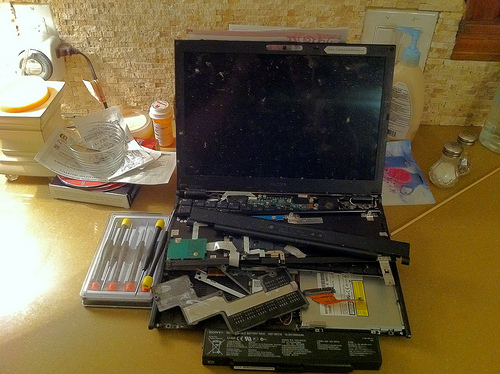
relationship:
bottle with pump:
[399, 30, 424, 138] [399, 24, 424, 71]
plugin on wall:
[51, 37, 80, 63] [123, 15, 147, 69]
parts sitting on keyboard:
[209, 221, 281, 285] [291, 259, 345, 299]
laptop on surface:
[158, 27, 421, 330] [449, 271, 479, 355]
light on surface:
[26, 223, 63, 293] [449, 271, 479, 355]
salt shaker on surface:
[426, 144, 467, 188] [449, 271, 479, 355]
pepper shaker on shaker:
[449, 131, 478, 154] [432, 142, 452, 173]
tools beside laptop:
[109, 217, 156, 294] [158, 27, 421, 330]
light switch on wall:
[368, 10, 400, 43] [123, 15, 147, 69]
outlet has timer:
[27, 14, 57, 49] [18, 47, 53, 79]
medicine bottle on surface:
[147, 97, 174, 145] [449, 271, 479, 355]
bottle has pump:
[399, 30, 424, 138] [399, 24, 424, 71]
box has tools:
[135, 215, 150, 226] [109, 217, 156, 294]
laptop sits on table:
[158, 27, 421, 330] [37, 191, 70, 225]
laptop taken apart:
[158, 27, 421, 330] [185, 186, 254, 221]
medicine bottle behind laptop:
[147, 97, 174, 145] [158, 27, 421, 330]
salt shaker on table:
[426, 144, 467, 188] [37, 191, 70, 225]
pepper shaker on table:
[449, 131, 478, 154] [37, 191, 70, 225]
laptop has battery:
[158, 27, 421, 330] [204, 327, 384, 369]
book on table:
[110, 188, 130, 205] [37, 191, 70, 225]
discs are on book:
[65, 176, 104, 191] [110, 188, 130, 205]